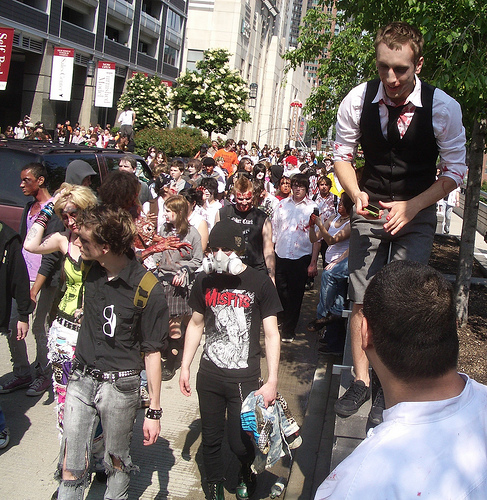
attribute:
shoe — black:
[335, 372, 373, 417]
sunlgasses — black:
[97, 295, 126, 342]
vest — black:
[352, 74, 441, 215]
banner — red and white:
[0, 26, 20, 100]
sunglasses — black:
[101, 304, 120, 337]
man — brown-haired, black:
[328, 21, 469, 415]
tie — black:
[365, 100, 419, 149]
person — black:
[21, 180, 104, 497]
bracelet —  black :
[144, 398, 168, 428]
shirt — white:
[270, 192, 317, 257]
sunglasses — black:
[214, 184, 290, 227]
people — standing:
[17, 143, 363, 404]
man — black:
[57, 203, 173, 496]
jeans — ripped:
[52, 369, 141, 496]